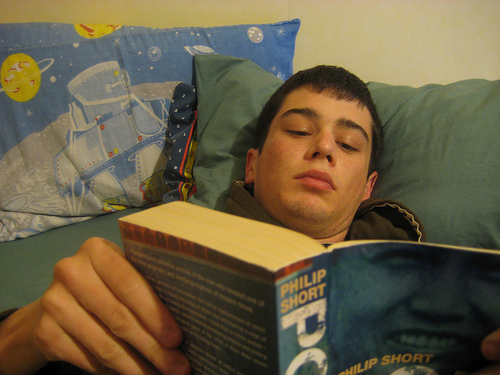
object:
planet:
[1, 52, 47, 105]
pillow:
[0, 22, 295, 247]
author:
[277, 267, 325, 317]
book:
[112, 200, 500, 375]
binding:
[274, 252, 330, 374]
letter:
[283, 299, 329, 353]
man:
[0, 61, 500, 374]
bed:
[0, 80, 500, 324]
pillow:
[186, 47, 499, 249]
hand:
[1, 234, 191, 375]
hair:
[251, 63, 385, 174]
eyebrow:
[275, 105, 319, 117]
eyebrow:
[337, 118, 372, 142]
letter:
[285, 347, 331, 375]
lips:
[292, 176, 338, 192]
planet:
[72, 22, 124, 43]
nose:
[306, 129, 337, 164]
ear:
[243, 147, 257, 186]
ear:
[364, 170, 382, 205]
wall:
[0, 0, 500, 88]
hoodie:
[343, 197, 426, 243]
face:
[333, 242, 500, 374]